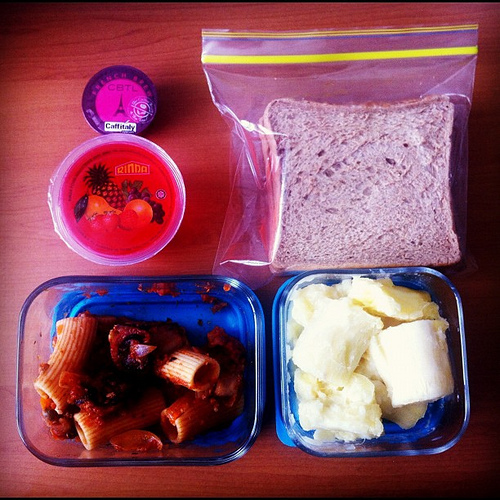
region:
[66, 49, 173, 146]
cup of coffee mix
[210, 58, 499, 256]
sandwich in plastic bag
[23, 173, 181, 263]
bowl of mixed fruit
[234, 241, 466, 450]
bowl of buttered potatoes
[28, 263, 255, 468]
bowl of meaty pasta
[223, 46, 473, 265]
yellow seal on sandwich bag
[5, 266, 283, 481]
blue bowl with pasta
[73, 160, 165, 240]
fruits on cup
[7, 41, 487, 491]
lunch on brown table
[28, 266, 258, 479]
blue lid under pasta bowl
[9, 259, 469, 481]
The containers hold food.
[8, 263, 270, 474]
The container holds pasta.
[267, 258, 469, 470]
The container holds cheese.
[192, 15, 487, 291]
The bag contains a sandwich.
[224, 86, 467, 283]
The sandwich is made of wheat bread.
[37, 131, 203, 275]
A container of jello is on the table.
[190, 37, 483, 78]
A yellow stripe is on the bag.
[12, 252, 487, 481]
The containers are open.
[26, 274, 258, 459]
The pasta is coated with a sauce.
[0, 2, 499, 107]
The tabletop is wood.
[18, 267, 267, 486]
rectangle glass container with blue lid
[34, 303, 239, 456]
serving of baked ziti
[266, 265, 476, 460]
square food storage container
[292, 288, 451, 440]
serving of mashed potatos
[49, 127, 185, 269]
container of fruit juice with foil lid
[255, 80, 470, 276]
slices of wheat bread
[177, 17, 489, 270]
sandwich in a Ziplock bag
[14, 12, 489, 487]
packed lunch sitting on a desk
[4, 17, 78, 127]
wooden venner table top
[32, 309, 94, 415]
cooked pasta dish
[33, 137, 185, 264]
a closed tropical fruit cup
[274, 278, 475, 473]
a square glass container with a white food substance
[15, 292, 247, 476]
a clear container with large tube noodles and sauce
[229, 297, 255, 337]
a blue lid beneath the container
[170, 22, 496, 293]
a wheat bread sandwich inside a plastic baggie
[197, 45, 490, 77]
a yellow strip on a plastic bag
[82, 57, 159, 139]
a small container with an image of the eiffel tower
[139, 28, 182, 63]
a brown wooden smooth table top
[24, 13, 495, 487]
a group of food items together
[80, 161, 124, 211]
an image of a pineapple on a fruit cup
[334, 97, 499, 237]
a sandwich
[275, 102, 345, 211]
a sandwich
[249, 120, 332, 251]
a sandwich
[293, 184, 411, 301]
a sandwich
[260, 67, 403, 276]
a sandwich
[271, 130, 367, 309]
a sandwich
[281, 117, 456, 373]
a sandwich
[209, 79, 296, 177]
a sandwich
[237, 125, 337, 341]
a sandwich